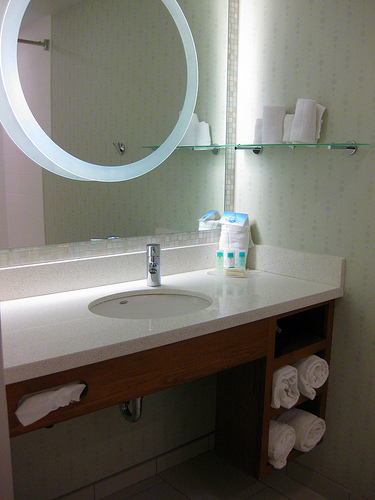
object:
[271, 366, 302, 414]
towel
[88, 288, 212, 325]
sink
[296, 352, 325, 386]
towel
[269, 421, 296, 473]
towel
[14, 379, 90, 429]
tissue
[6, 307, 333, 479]
cabinet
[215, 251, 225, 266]
shampoo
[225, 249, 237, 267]
conditioner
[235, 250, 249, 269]
lotion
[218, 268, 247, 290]
soap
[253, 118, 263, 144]
wash cloth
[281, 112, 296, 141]
wash cloth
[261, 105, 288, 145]
hand towel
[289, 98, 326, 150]
hand towel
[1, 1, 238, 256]
mirror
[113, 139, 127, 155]
hook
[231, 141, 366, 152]
shelf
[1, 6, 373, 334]
bathroom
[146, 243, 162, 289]
faucet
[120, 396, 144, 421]
pipe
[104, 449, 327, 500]
floor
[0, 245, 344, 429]
counter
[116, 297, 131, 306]
hole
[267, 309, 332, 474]
compartment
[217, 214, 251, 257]
towel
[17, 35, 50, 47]
shower curtain rod